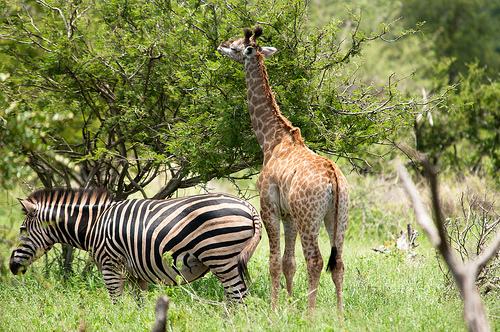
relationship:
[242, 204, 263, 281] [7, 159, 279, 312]
striped tail on zebra